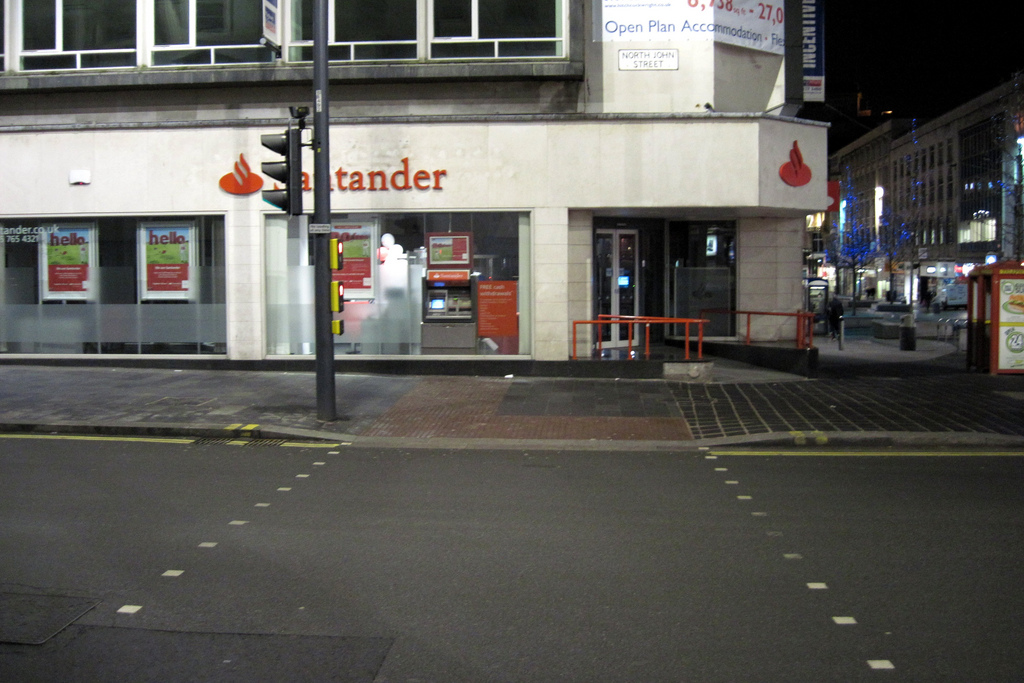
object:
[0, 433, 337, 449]
line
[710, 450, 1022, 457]
line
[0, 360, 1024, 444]
sidewalk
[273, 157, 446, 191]
letters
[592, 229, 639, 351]
doors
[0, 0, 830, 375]
store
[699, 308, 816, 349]
railing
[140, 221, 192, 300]
poster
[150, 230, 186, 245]
hello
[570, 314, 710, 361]
railing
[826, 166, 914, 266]
lights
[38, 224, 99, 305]
signs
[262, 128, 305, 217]
spotlight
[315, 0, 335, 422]
pole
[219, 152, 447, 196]
logo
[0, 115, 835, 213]
background